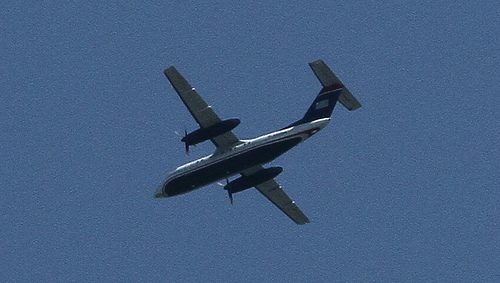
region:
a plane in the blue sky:
[131, 41, 375, 238]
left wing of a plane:
[149, 62, 239, 152]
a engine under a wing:
[171, 111, 242, 156]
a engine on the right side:
[207, 160, 316, 240]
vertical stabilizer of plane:
[294, 47, 364, 127]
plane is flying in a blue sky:
[1, 4, 496, 279]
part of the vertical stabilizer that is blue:
[307, 80, 344, 121]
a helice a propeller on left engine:
[160, 115, 206, 155]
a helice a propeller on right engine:
[215, 175, 247, 200]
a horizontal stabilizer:
[301, 51, 373, 116]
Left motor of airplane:
[176, 113, 247, 154]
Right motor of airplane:
[210, 170, 236, 208]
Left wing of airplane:
[153, 58, 243, 153]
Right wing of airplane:
[235, 158, 316, 230]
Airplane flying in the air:
[151, 56, 371, 223]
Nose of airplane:
[147, 163, 173, 203]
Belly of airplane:
[195, 143, 316, 183]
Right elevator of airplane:
[340, 75, 365, 110]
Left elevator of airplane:
[296, 46, 336, 86]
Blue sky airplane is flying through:
[7, 4, 494, 281]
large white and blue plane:
[98, 30, 363, 235]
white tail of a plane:
[295, 45, 375, 140]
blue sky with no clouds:
[20, 5, 480, 265]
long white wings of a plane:
[145, 45, 310, 245]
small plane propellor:
[163, 117, 208, 164]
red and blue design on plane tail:
[295, 73, 358, 153]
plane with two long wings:
[105, 35, 361, 241]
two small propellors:
[160, 110, 291, 222]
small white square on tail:
[306, 91, 336, 114]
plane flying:
[102, 31, 380, 253]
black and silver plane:
[135, 48, 369, 230]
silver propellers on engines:
[167, 126, 245, 202]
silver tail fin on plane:
[308, 57, 366, 119]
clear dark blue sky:
[20, 55, 138, 235]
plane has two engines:
[170, 112, 291, 208]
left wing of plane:
[160, 62, 246, 147]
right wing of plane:
[232, 166, 321, 228]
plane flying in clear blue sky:
[132, 42, 369, 248]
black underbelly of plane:
[160, 135, 323, 202]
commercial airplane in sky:
[146, 48, 363, 232]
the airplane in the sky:
[131, 55, 396, 255]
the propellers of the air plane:
[155, 125, 257, 207]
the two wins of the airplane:
[161, 73, 317, 234]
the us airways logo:
[290, 85, 355, 111]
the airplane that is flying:
[135, 5, 390, 270]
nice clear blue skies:
[40, 47, 130, 243]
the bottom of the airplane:
[161, 138, 343, 193]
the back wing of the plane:
[298, 55, 358, 95]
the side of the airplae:
[165, 140, 340, 160]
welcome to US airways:
[126, 54, 441, 207]